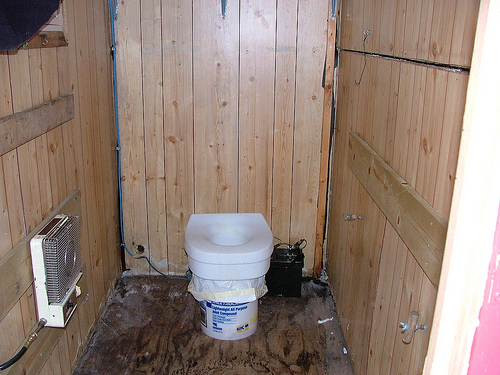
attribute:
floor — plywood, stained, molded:
[72, 274, 357, 375]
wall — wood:
[111, 2, 338, 288]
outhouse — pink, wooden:
[1, 1, 500, 375]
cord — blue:
[109, 2, 192, 282]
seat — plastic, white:
[182, 213, 275, 262]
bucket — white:
[199, 301, 256, 340]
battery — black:
[265, 249, 303, 298]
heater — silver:
[30, 212, 85, 329]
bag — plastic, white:
[185, 272, 271, 303]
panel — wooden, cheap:
[272, 1, 299, 248]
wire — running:
[319, 2, 339, 277]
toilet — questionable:
[186, 212, 273, 343]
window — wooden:
[1, 1, 68, 52]